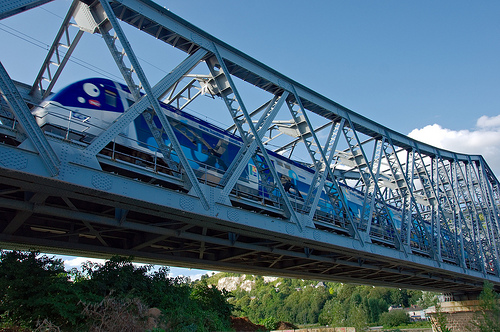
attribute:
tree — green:
[254, 286, 295, 327]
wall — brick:
[428, 298, 490, 325]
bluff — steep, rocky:
[149, 267, 491, 322]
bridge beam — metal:
[203, 55, 365, 151]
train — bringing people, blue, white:
[30, 75, 485, 268]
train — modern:
[44, 69, 490, 291]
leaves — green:
[76, 268, 230, 325]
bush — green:
[133, 262, 173, 304]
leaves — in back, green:
[14, 253, 467, 330]